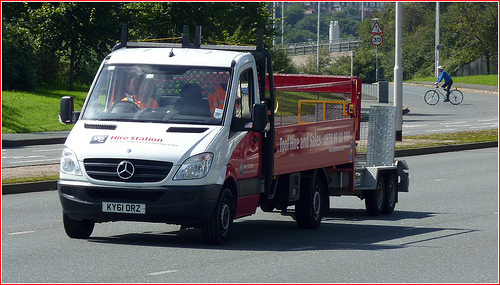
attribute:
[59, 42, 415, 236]
truck — white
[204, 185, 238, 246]
tire — wheel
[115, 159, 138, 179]
emblem — mercedes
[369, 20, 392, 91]
sign — triangular, red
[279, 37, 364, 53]
fence — silver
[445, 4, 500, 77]
tree — green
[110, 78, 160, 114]
man — driver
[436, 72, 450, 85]
shirt — blue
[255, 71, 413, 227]
trailer — red